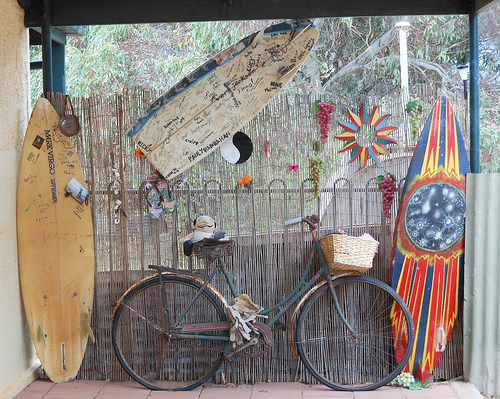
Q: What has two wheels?
A: Bicycle.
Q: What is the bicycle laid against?
A: Fence.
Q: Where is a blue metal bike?
A: Ground.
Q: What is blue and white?
A: Surf board.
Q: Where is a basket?
A: At the front of the bike.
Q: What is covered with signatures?
A: Surfboard.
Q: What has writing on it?
A: Surfboard.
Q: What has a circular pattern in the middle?
A: Surfboard.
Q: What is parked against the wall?
A: A bicycle.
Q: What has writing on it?
A: Tan surfboard.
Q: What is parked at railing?
A: A blue bicycle.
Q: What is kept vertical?
A: Surfboard.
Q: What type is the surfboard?
A: Wooden.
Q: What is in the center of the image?
A: Bicycle.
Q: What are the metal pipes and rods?
A: Railing type.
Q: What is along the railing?
A: Straw fence.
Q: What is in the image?
A: Ceiling of the balcony.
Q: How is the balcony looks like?
A: Yellow.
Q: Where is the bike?
A: Middle of the picture.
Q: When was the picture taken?
A: Daytime.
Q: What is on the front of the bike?
A: Basket.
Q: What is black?
A: Bike tires.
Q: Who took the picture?
A: Woman.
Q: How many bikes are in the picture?
A: One.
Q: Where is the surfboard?
A: Left of the bike.